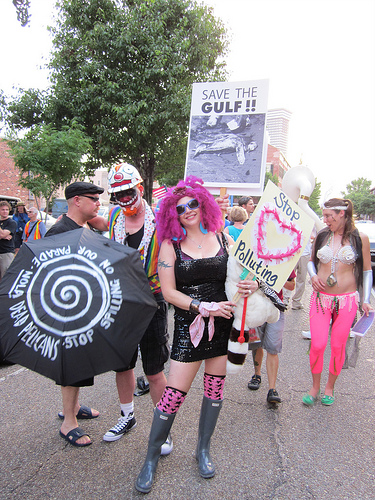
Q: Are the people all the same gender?
A: No, they are both male and female.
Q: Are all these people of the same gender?
A: No, they are both male and female.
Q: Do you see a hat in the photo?
A: Yes, there is a hat.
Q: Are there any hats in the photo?
A: Yes, there is a hat.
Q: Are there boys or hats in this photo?
A: Yes, there is a hat.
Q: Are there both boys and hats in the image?
A: No, there is a hat but no boys.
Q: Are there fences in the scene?
A: No, there are no fences.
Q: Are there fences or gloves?
A: No, there are no fences or gloves.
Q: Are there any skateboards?
A: No, there are no skateboards.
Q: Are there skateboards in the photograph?
A: No, there are no skateboards.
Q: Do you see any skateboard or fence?
A: No, there are no skateboards or fences.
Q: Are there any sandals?
A: Yes, there are sandals.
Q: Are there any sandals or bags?
A: Yes, there are sandals.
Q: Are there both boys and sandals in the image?
A: No, there are sandals but no boys.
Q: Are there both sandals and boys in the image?
A: No, there are sandals but no boys.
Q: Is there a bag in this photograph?
A: No, there are no bags.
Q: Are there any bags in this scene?
A: No, there are no bags.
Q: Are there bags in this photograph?
A: No, there are no bags.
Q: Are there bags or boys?
A: No, there are no bags or boys.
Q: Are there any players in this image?
A: No, there are no players.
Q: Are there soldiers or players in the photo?
A: No, there are no players or soldiers.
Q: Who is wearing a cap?
A: The man is wearing a cap.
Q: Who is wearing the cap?
A: The man is wearing a cap.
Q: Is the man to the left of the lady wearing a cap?
A: Yes, the man is wearing a cap.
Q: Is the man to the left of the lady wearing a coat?
A: No, the man is wearing a cap.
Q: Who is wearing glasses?
A: The man is wearing glasses.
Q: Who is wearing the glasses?
A: The man is wearing glasses.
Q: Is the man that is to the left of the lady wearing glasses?
A: Yes, the man is wearing glasses.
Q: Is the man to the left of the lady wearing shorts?
A: No, the man is wearing glasses.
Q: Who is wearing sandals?
A: The man is wearing sandals.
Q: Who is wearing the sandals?
A: The man is wearing sandals.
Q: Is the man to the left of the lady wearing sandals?
A: Yes, the man is wearing sandals.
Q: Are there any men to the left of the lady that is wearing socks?
A: Yes, there is a man to the left of the lady.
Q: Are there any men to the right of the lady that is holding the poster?
A: No, the man is to the left of the lady.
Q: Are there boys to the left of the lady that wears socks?
A: No, there is a man to the left of the lady.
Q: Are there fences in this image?
A: No, there are no fences.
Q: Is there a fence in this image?
A: No, there are no fences.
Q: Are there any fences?
A: No, there are no fences.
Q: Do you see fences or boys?
A: No, there are no fences or boys.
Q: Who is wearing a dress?
A: The lady is wearing a dress.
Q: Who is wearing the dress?
A: The lady is wearing a dress.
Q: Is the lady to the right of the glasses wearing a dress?
A: Yes, the lady is wearing a dress.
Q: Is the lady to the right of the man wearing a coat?
A: No, the lady is wearing a dress.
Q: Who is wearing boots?
A: The lady is wearing boots.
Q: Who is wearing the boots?
A: The lady is wearing boots.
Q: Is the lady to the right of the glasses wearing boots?
A: Yes, the lady is wearing boots.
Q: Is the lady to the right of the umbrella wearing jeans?
A: No, the lady is wearing boots.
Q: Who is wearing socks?
A: The lady is wearing socks.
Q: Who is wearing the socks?
A: The lady is wearing socks.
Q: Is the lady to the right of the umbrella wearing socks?
A: Yes, the lady is wearing socks.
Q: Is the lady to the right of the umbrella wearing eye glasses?
A: No, the lady is wearing socks.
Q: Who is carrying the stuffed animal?
A: The lady is carrying the stuffed animal.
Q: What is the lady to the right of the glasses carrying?
A: The lady is carrying a stuffed animal.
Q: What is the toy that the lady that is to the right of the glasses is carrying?
A: The toy is a stuffed animal.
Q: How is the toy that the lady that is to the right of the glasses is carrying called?
A: The toy is a stuffed animal.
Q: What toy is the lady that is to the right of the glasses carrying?
A: The lady is carrying a stuffed animal.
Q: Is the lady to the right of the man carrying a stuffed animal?
A: Yes, the lady is carrying a stuffed animal.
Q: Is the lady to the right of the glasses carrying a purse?
A: No, the lady is carrying a stuffed animal.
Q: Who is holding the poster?
A: The lady is holding the poster.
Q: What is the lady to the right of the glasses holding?
A: The lady is holding the poster.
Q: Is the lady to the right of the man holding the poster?
A: Yes, the lady is holding the poster.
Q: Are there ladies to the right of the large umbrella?
A: Yes, there is a lady to the right of the umbrella.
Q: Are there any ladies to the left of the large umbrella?
A: No, the lady is to the right of the umbrella.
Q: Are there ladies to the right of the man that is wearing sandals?
A: Yes, there is a lady to the right of the man.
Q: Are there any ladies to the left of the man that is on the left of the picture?
A: No, the lady is to the right of the man.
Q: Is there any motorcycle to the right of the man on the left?
A: No, there is a lady to the right of the man.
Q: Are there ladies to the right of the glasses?
A: Yes, there is a lady to the right of the glasses.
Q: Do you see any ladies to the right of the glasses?
A: Yes, there is a lady to the right of the glasses.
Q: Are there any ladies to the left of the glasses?
A: No, the lady is to the right of the glasses.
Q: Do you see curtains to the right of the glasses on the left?
A: No, there is a lady to the right of the glasses.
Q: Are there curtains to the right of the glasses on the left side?
A: No, there is a lady to the right of the glasses.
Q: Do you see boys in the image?
A: No, there are no boys.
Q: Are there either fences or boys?
A: No, there are no boys or fences.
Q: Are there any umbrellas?
A: Yes, there is an umbrella.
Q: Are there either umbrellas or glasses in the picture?
A: Yes, there is an umbrella.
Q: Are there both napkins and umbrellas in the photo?
A: No, there is an umbrella but no napkins.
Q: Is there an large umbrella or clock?
A: Yes, there is a large umbrella.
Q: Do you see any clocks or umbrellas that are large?
A: Yes, the umbrella is large.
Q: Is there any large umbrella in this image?
A: Yes, there is a large umbrella.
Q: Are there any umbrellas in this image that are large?
A: Yes, there is an umbrella that is large.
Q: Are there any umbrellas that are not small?
A: Yes, there is a large umbrella.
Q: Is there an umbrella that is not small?
A: Yes, there is a large umbrella.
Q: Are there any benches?
A: No, there are no benches.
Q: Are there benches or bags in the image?
A: No, there are no benches or bags.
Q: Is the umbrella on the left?
A: Yes, the umbrella is on the left of the image.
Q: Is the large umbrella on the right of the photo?
A: No, the umbrella is on the left of the image.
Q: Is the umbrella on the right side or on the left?
A: The umbrella is on the left of the image.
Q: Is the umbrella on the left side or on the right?
A: The umbrella is on the left of the image.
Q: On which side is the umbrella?
A: The umbrella is on the left of the image.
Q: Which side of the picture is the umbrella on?
A: The umbrella is on the left of the image.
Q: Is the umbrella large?
A: Yes, the umbrella is large.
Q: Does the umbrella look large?
A: Yes, the umbrella is large.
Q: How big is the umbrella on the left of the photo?
A: The umbrella is large.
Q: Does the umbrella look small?
A: No, the umbrella is large.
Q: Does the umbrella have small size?
A: No, the umbrella is large.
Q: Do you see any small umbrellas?
A: No, there is an umbrella but it is large.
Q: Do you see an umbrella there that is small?
A: No, there is an umbrella but it is large.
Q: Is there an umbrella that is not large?
A: No, there is an umbrella but it is large.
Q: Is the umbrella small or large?
A: The umbrella is large.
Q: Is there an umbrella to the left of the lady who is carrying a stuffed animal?
A: Yes, there is an umbrella to the left of the lady.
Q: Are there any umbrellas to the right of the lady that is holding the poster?
A: No, the umbrella is to the left of the lady.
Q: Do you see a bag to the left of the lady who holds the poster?
A: No, there is an umbrella to the left of the lady.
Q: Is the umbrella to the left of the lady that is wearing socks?
A: Yes, the umbrella is to the left of the lady.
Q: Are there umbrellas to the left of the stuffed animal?
A: Yes, there is an umbrella to the left of the stuffed animal.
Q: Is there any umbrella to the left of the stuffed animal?
A: Yes, there is an umbrella to the left of the stuffed animal.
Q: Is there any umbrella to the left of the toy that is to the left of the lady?
A: Yes, there is an umbrella to the left of the stuffed animal.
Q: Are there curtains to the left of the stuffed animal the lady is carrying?
A: No, there is an umbrella to the left of the stuffed animal.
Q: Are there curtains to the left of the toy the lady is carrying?
A: No, there is an umbrella to the left of the stuffed animal.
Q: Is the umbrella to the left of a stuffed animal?
A: Yes, the umbrella is to the left of a stuffed animal.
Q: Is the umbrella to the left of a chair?
A: No, the umbrella is to the left of a stuffed animal.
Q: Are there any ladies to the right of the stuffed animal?
A: Yes, there is a lady to the right of the stuffed animal.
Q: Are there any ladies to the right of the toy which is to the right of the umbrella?
A: Yes, there is a lady to the right of the stuffed animal.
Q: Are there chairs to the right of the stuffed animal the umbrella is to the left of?
A: No, there is a lady to the right of the stuffed animal.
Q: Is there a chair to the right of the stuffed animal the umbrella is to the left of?
A: No, there is a lady to the right of the stuffed animal.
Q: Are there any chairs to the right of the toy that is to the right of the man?
A: No, there is a lady to the right of the stuffed animal.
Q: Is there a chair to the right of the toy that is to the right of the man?
A: No, there is a lady to the right of the stuffed animal.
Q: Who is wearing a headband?
A: The lady is wearing a headband.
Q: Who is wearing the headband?
A: The lady is wearing a headband.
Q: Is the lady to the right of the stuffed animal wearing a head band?
A: Yes, the lady is wearing a head band.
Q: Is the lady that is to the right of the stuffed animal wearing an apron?
A: No, the lady is wearing a head band.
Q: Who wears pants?
A: The lady wears pants.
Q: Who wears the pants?
A: The lady wears pants.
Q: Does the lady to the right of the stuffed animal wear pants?
A: Yes, the lady wears pants.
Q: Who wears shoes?
A: The lady wears shoes.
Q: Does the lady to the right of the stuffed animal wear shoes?
A: Yes, the lady wears shoes.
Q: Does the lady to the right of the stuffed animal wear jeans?
A: No, the lady wears shoes.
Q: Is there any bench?
A: No, there are no benches.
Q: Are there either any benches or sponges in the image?
A: No, there are no benches or sponges.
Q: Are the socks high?
A: Yes, the socks are high.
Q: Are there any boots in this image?
A: Yes, there are boots.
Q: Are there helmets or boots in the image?
A: Yes, there are boots.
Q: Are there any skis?
A: No, there are no skis.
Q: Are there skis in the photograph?
A: No, there are no skis.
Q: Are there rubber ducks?
A: No, there are no rubber ducks.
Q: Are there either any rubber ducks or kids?
A: No, there are no rubber ducks or kids.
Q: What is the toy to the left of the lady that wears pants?
A: The toy is a stuffed animal.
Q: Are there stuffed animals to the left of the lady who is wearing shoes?
A: Yes, there is a stuffed animal to the left of the lady.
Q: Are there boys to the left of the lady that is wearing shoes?
A: No, there is a stuffed animal to the left of the lady.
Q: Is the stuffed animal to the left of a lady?
A: Yes, the stuffed animal is to the left of a lady.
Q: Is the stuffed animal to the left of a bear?
A: No, the stuffed animal is to the left of a lady.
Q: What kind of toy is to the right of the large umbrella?
A: The toy is a stuffed animal.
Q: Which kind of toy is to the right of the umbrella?
A: The toy is a stuffed animal.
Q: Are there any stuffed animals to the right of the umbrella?
A: Yes, there is a stuffed animal to the right of the umbrella.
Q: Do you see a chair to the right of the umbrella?
A: No, there is a stuffed animal to the right of the umbrella.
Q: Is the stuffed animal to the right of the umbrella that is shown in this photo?
A: Yes, the stuffed animal is to the right of the umbrella.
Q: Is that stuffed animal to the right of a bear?
A: No, the stuffed animal is to the right of the umbrella.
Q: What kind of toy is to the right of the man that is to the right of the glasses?
A: The toy is a stuffed animal.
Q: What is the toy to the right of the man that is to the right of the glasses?
A: The toy is a stuffed animal.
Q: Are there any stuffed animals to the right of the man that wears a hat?
A: Yes, there is a stuffed animal to the right of the man.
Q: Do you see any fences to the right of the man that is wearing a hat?
A: No, there is a stuffed animal to the right of the man.